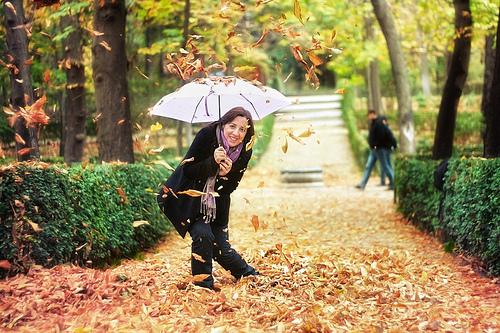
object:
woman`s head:
[206, 106, 255, 148]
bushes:
[2, 155, 175, 272]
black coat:
[157, 121, 253, 239]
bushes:
[390, 152, 497, 249]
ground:
[312, 89, 336, 136]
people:
[355, 108, 398, 191]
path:
[0, 95, 499, 333]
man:
[156, 106, 259, 291]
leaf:
[275, 241, 290, 260]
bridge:
[247, 78, 379, 178]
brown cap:
[366, 109, 377, 117]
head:
[367, 107, 378, 119]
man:
[352, 106, 397, 188]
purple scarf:
[197, 125, 243, 224]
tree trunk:
[91, 0, 134, 164]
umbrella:
[147, 76, 294, 147]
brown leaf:
[2, 94, 50, 129]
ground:
[102, 202, 401, 308]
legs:
[187, 210, 215, 290]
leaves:
[2, 0, 500, 332]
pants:
[187, 210, 257, 289]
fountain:
[279, 167, 323, 186]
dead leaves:
[49, 246, 497, 328]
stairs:
[251, 94, 369, 188]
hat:
[367, 107, 377, 116]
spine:
[190, 96, 205, 124]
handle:
[217, 95, 223, 146]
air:
[366, 25, 437, 91]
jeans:
[360, 147, 395, 188]